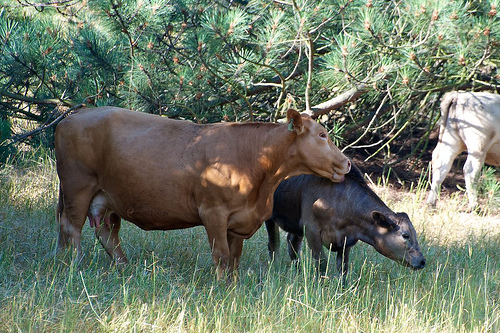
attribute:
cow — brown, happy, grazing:
[66, 80, 387, 287]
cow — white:
[431, 78, 498, 185]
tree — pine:
[91, 1, 444, 116]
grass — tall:
[4, 185, 459, 320]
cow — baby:
[284, 153, 430, 282]